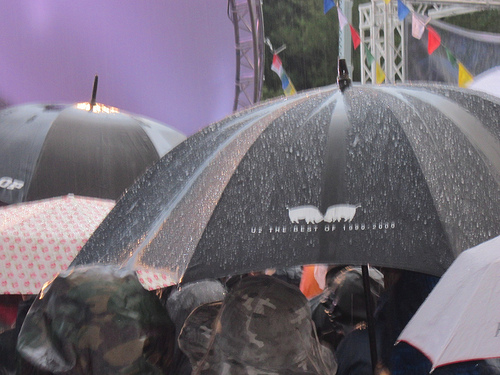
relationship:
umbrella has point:
[60, 58, 500, 375] [333, 57, 351, 88]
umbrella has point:
[0, 105, 190, 206] [87, 74, 99, 106]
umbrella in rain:
[60, 58, 500, 375] [327, 31, 444, 242]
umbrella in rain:
[391, 233, 498, 373] [327, 31, 444, 242]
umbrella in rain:
[0, 193, 115, 292] [327, 31, 444, 242]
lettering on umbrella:
[249, 216, 399, 236] [68, 58, 498, 373]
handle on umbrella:
[360, 265, 378, 374] [68, 58, 498, 373]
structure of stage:
[360, 6, 496, 88] [1, 1, 496, 136]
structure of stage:
[334, 0, 354, 83] [1, 1, 496, 136]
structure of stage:
[226, 2, 271, 113] [1, 1, 496, 136]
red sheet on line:
[421, 23, 441, 54] [383, 2, 498, 58]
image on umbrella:
[278, 200, 366, 227] [60, 58, 500, 375]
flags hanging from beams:
[320, 2, 474, 86] [355, 2, 410, 80]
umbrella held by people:
[60, 58, 500, 375] [41, 268, 448, 373]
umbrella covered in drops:
[60, 58, 500, 375] [280, 143, 295, 156]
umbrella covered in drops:
[60, 58, 500, 375] [445, 188, 461, 198]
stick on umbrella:
[86, 72, 100, 105] [60, 58, 500, 375]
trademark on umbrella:
[283, 197, 365, 230] [60, 58, 500, 375]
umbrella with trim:
[60, 58, 500, 375] [399, 334, 479, 373]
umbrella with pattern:
[0, 193, 115, 292] [9, 205, 71, 265]